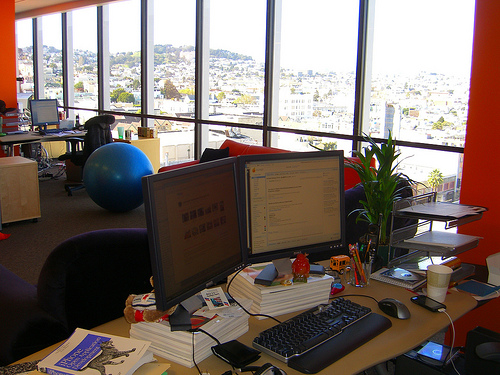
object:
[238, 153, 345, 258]
monitor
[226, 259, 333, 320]
books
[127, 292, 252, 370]
books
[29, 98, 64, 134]
computer moniter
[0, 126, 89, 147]
desk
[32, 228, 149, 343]
desk chair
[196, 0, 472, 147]
windows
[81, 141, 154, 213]
ball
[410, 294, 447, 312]
cellphone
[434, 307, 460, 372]
charger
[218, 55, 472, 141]
city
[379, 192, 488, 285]
desktop tray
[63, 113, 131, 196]
chair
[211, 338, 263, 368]
leather wallet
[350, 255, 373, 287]
cup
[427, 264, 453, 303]
cup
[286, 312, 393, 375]
arm rest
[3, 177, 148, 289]
floor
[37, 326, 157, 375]
book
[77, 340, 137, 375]
picture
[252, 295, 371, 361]
keyboard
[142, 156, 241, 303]
monitor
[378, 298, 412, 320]
mouse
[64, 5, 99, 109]
window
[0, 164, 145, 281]
carpet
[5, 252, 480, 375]
desk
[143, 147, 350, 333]
computer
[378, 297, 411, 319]
computer mouse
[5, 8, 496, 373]
room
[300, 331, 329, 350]
keys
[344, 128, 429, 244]
plant